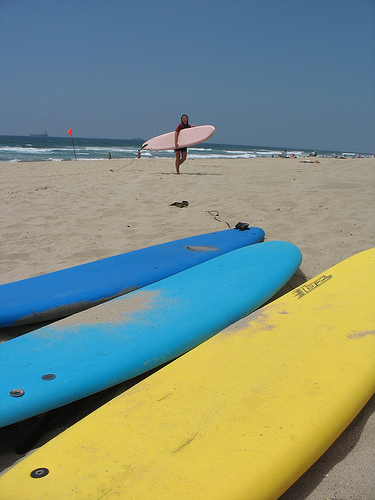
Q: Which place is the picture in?
A: It is at the plain.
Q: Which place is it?
A: It is a plain.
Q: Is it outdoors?
A: Yes, it is outdoors.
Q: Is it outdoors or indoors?
A: It is outdoors.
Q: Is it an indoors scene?
A: No, it is outdoors.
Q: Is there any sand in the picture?
A: Yes, there is sand.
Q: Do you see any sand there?
A: Yes, there is sand.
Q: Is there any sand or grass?
A: Yes, there is sand.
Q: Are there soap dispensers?
A: No, there are no soap dispensers.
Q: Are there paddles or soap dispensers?
A: No, there are no soap dispensers or paddles.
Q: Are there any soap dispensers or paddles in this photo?
A: No, there are no soap dispensers or paddles.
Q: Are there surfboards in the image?
A: Yes, there is a surfboard.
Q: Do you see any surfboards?
A: Yes, there is a surfboard.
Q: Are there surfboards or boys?
A: Yes, there is a surfboard.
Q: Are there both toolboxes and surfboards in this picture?
A: No, there is a surfboard but no toolboxes.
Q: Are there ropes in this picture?
A: No, there are no ropes.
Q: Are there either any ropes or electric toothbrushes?
A: No, there are no ropes or electric toothbrushes.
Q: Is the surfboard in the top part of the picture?
A: Yes, the surfboard is in the top of the image.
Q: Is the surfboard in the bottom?
A: No, the surfboard is in the top of the image.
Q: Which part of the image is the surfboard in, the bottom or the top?
A: The surfboard is in the top of the image.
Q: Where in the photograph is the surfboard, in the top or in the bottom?
A: The surfboard is in the top of the image.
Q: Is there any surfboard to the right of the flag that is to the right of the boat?
A: Yes, there is a surfboard to the right of the flag.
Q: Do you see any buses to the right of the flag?
A: No, there is a surfboard to the right of the flag.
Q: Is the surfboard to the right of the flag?
A: Yes, the surfboard is to the right of the flag.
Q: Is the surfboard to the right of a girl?
A: No, the surfboard is to the right of the flag.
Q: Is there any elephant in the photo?
A: No, there are no elephants.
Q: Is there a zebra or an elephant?
A: No, there are no elephants or zebras.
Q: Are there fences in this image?
A: No, there are no fences.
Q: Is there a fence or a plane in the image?
A: No, there are no fences or airplanes.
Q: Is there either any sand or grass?
A: Yes, there is sand.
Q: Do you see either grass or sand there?
A: Yes, there is sand.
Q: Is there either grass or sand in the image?
A: Yes, there is sand.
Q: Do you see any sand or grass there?
A: Yes, there is sand.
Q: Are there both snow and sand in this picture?
A: No, there is sand but no snow.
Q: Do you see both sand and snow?
A: No, there is sand but no snow.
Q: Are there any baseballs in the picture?
A: No, there are no baseballs.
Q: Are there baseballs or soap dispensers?
A: No, there are no baseballs or soap dispensers.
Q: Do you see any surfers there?
A: Yes, there is a surfer.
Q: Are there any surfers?
A: Yes, there is a surfer.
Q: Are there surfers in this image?
A: Yes, there is a surfer.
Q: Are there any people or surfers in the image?
A: Yes, there is a surfer.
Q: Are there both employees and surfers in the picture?
A: No, there is a surfer but no employees.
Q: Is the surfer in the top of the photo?
A: Yes, the surfer is in the top of the image.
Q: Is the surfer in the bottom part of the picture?
A: No, the surfer is in the top of the image.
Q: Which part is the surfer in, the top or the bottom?
A: The surfer is in the top of the image.